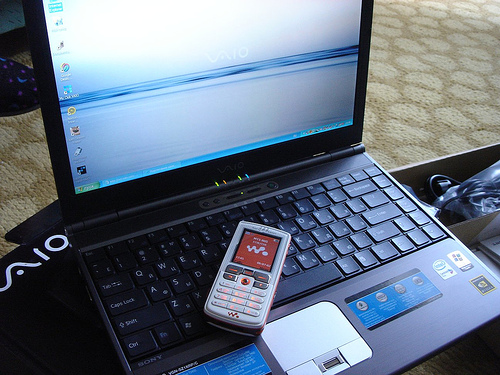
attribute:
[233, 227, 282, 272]
logo — red